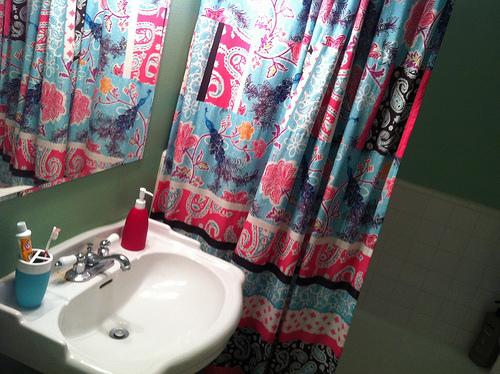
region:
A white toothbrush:
[45, 223, 60, 256]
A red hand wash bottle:
[117, 155, 154, 248]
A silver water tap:
[57, 249, 99, 280]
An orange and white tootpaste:
[15, 219, 36, 259]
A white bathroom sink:
[57, 221, 238, 372]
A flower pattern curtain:
[183, 99, 350, 256]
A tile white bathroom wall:
[395, 229, 456, 319]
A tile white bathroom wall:
[460, 212, 496, 285]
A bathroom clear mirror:
[13, 63, 121, 153]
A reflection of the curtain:
[2, 56, 154, 163]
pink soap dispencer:
[119, 183, 153, 251]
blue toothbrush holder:
[14, 220, 58, 311]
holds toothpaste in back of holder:
[15, 220, 35, 259]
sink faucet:
[54, 227, 128, 279]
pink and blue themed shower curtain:
[146, 1, 448, 372]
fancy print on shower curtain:
[151, 4, 444, 371]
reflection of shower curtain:
[1, 0, 167, 198]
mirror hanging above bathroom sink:
[0, 5, 169, 195]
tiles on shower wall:
[356, 174, 498, 363]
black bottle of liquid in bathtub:
[470, 288, 498, 370]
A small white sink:
[0, 210, 257, 370]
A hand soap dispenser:
[115, 185, 155, 260]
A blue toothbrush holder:
[5, 220, 60, 315]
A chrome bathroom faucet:
[60, 230, 130, 280]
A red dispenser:
[110, 205, 175, 265]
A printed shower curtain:
[180, 15, 405, 245]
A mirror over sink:
[15, 5, 155, 180]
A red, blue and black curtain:
[190, 30, 350, 230]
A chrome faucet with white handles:
[52, 231, 127, 271]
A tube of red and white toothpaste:
[13, 219, 39, 257]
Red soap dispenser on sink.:
[125, 196, 160, 247]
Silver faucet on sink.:
[71, 231, 146, 281]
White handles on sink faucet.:
[51, 242, 131, 264]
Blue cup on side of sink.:
[6, 233, 73, 338]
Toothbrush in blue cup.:
[40, 216, 72, 259]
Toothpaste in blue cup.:
[5, 220, 47, 263]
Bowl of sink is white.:
[56, 276, 227, 358]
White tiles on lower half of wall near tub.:
[395, 220, 466, 348]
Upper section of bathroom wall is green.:
[446, 88, 488, 175]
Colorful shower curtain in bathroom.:
[242, 43, 321, 270]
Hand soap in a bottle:
[119, 184, 156, 252]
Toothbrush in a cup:
[11, 213, 62, 315]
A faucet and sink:
[1, 213, 247, 370]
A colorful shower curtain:
[149, 0, 452, 372]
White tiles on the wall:
[353, 177, 498, 354]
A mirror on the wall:
[1, 0, 169, 204]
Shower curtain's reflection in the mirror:
[1, 0, 165, 194]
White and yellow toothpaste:
[10, 216, 40, 268]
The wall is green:
[398, 0, 498, 214]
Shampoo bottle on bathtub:
[458, 293, 498, 371]